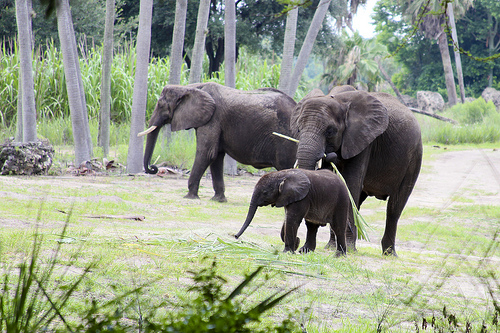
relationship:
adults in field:
[134, 81, 297, 203] [9, 160, 493, 324]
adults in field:
[134, 81, 297, 203] [9, 86, 498, 327]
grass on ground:
[1, 134, 497, 331] [3, 142, 498, 330]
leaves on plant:
[0, 122, 498, 331] [1, 114, 499, 331]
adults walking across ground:
[142, 79, 299, 201] [3, 142, 498, 330]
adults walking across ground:
[288, 81, 424, 258] [3, 142, 498, 330]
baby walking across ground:
[231, 165, 352, 256] [3, 142, 498, 330]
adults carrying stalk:
[278, 84, 424, 259] [270, 127, 372, 247]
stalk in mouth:
[270, 127, 372, 247] [293, 138, 329, 159]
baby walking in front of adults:
[231, 167, 351, 259] [134, 81, 297, 203]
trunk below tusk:
[141, 122, 158, 176] [137, 122, 157, 137]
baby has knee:
[231, 167, 351, 259] [279, 222, 286, 244]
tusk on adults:
[141, 118, 173, 140] [134, 81, 297, 203]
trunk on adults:
[141, 122, 159, 174] [134, 81, 297, 203]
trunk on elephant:
[234, 205, 257, 240] [232, 167, 349, 258]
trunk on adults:
[297, 135, 324, 169] [278, 84, 424, 259]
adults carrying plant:
[278, 84, 424, 259] [270, 130, 370, 242]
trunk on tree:
[141, 122, 158, 176] [51, 21, 103, 177]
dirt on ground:
[405, 147, 499, 213] [3, 142, 498, 330]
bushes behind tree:
[0, 31, 311, 126] [13, 0, 36, 140]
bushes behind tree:
[0, 31, 311, 126] [53, 0, 96, 167]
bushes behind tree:
[0, 31, 311, 126] [97, 0, 116, 156]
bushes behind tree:
[0, 31, 311, 126] [128, 0, 154, 174]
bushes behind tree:
[0, 31, 311, 126] [163, 0, 188, 140]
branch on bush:
[409, 302, 442, 331] [372, 227, 497, 331]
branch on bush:
[439, 299, 466, 329] [372, 227, 497, 331]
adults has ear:
[134, 81, 297, 203] [168, 85, 213, 132]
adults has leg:
[134, 81, 297, 203] [185, 115, 222, 198]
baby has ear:
[231, 167, 351, 259] [275, 167, 308, 211]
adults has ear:
[134, 81, 297, 203] [174, 85, 217, 140]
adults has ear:
[278, 84, 424, 259] [339, 93, 396, 162]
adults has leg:
[278, 84, 424, 259] [380, 175, 417, 257]